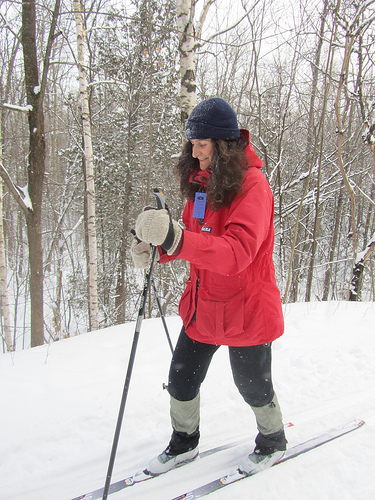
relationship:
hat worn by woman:
[182, 97, 244, 143] [128, 94, 290, 484]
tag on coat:
[191, 192, 209, 224] [167, 129, 284, 351]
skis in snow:
[63, 410, 369, 500] [3, 300, 372, 494]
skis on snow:
[63, 410, 369, 500] [3, 300, 372, 494]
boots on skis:
[145, 429, 292, 477] [63, 410, 369, 500]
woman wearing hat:
[128, 94, 290, 484] [182, 97, 244, 143]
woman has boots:
[128, 94, 290, 484] [145, 429, 292, 477]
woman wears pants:
[128, 94, 290, 484] [165, 323, 285, 454]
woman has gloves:
[128, 94, 290, 484] [132, 184, 187, 267]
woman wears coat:
[128, 94, 290, 484] [167, 129, 284, 351]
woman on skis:
[128, 94, 290, 484] [63, 410, 369, 500]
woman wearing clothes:
[128, 94, 290, 484] [170, 150, 290, 468]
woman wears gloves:
[128, 94, 290, 484] [132, 184, 187, 267]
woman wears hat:
[128, 94, 290, 484] [182, 97, 244, 143]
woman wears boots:
[128, 94, 290, 484] [145, 429, 292, 477]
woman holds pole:
[128, 94, 290, 484] [98, 243, 157, 499]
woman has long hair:
[128, 94, 290, 484] [205, 133, 248, 207]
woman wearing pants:
[128, 94, 290, 484] [165, 323, 285, 454]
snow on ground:
[3, 300, 372, 494] [19, 359, 336, 490]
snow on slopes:
[3, 300, 372, 494] [22, 354, 363, 489]